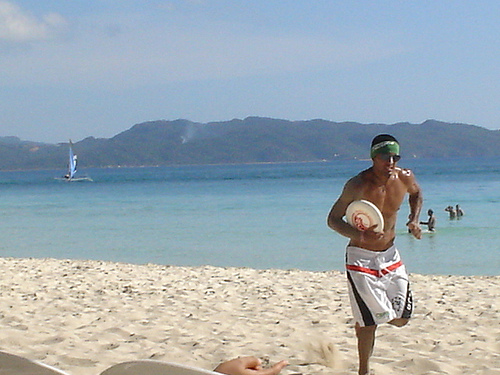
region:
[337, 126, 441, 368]
a man running on the beach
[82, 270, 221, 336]
uneven sandy surface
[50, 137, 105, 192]
a sailboat in the water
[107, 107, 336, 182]
a mountainside with trees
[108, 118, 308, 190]
a mountain beside the water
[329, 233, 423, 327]
a person wearing white, red, and black shorts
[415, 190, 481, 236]
a group of people in the water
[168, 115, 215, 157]
smoke on the side of a mountain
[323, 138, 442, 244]
a man without a shirt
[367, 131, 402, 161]
a person wearing a headband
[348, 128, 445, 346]
A man on the beach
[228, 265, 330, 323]
A white sand beach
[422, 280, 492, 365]
A white sand beach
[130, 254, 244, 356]
A white sand beach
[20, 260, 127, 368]
A white sand beach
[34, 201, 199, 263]
A blue water surface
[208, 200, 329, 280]
A blue water surface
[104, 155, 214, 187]
A blue water surface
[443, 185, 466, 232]
A person in the water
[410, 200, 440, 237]
A person in the water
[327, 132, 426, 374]
Man running on the beach with a Frisbee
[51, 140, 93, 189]
Sailboat in the water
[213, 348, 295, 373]
Hand pointing toward man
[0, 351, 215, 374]
Tops of plastic chairs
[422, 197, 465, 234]
People standing in the water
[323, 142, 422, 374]
Man wearing white, black and red swim trunks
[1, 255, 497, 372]
Sandy stretch of shoreline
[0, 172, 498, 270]
Calm blue water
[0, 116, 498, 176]
Mountains in the distance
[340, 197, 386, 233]
White Frisbee in man's arm.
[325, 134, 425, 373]
Man running in the sand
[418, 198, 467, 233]
People in the water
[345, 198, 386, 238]
White Frisbee in man's arm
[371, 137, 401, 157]
Green visor on man's head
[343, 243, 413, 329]
White, black and red swimsuit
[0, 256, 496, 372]
Sandy beach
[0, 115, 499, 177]
Mountains in the background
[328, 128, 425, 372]
this is the man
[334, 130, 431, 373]
the man is running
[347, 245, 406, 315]
he is wearing shorts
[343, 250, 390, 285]
the short is white in color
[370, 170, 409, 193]
the man is bare chested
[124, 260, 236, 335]
this is the beach sand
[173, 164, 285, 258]
this is the sea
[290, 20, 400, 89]
this is the sky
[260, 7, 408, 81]
the sky is clear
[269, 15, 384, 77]
the sky is blue in color